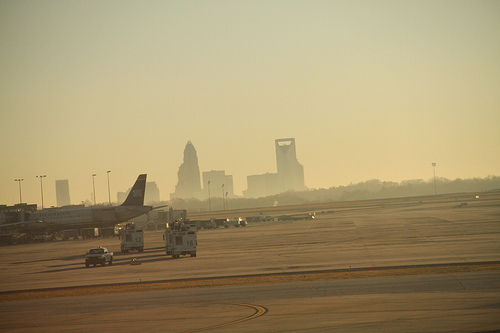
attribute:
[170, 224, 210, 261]
truck — white, transportation, boxy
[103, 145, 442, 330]
airport — tarmac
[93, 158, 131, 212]
pole — light, tall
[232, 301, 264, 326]
line — yellow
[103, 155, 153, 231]
tail — plane, dark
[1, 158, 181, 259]
plane — parked, large, white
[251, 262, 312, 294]
grass — strip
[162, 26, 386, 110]
sky — cloudy, gray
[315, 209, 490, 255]
runway — concrete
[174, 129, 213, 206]
building — tall, rectangular, conical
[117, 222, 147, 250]
vehicle — white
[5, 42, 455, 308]
background — airport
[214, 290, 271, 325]
ground — yellow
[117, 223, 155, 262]
car — large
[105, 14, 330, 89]
day — hazy